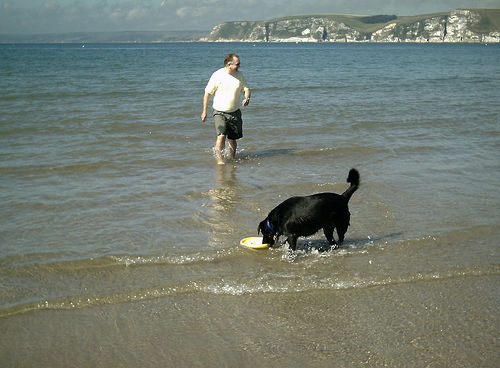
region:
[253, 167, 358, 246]
A black dog.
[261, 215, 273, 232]
A blue collar on a black dog.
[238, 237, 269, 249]
A yellow disc in the water.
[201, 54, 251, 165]
A brown haired man in glasses walking in the water.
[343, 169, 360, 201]
Black dog tail.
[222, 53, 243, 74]
Head of a walking man with brown hair and sunglasses.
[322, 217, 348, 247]
Two black back legs of a dog.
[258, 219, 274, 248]
Black head of a dog.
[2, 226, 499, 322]
Two small waves coming onto shore by a dog.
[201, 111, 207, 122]
A man's right hand.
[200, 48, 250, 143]
this is a man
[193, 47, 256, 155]
the man is walking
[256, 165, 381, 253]
this is a dog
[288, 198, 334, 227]
the dog is black in collor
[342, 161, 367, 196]
this is the tail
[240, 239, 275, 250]
this is a frisbee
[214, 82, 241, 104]
this is the belly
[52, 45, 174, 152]
the wall is calm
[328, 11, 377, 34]
this is a hill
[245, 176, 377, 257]
a dog in the water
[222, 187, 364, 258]
a dog grabbing a frisbee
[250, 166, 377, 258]
a black dog with a blue collar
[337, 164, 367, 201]
the tail of a dog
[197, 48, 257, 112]
a person wearing a short sleeved shirt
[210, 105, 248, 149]
a person wearing shorts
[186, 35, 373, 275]
a man and dog in the water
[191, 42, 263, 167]
a man walking in the water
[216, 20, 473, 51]
a rock cliff face beside the water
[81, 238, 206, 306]
waves rolling onto the shore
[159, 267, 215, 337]
part f a wave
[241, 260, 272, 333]
part of a shore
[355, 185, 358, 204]
part fo a tail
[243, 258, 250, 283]
edge fo a shore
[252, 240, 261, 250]
edge of a dish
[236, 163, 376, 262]
dog in the water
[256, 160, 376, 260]
black fur on the dog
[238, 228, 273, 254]
yellow frisbee in the water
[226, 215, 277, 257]
frisbee in the dog's mouth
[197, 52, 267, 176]
man walking in the water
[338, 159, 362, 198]
tail is sticking up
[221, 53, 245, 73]
head is turned to the side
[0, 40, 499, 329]
body of water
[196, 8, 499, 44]
land in the distance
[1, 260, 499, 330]
small wave rolling into shore